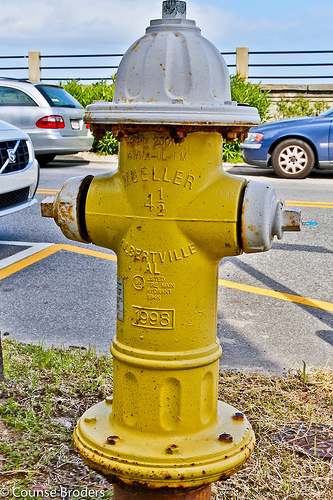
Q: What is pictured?
A: A hydrant.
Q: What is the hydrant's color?
A: Yellow.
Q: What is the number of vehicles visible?
A: Three.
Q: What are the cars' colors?
A: Blue and silver.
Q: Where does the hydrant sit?
A: Dried grass.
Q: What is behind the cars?
A: Green foliage.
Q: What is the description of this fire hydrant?
A: Yellow with white top and sides.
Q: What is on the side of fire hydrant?
A: Writing and year.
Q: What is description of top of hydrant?
A: White.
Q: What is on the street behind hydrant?
A: Yellow and white street markings.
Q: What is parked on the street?
A: Cars.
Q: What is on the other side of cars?
A: A metal rail with cement post.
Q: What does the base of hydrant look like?
A: Round with nuts and bolts.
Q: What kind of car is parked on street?
A: A van.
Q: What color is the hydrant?
A: Yellow.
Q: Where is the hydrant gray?
A: On top and on the ends.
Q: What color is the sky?
A: Blue.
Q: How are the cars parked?
A: In spaces along the road.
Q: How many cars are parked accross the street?
A: Two.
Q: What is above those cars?
A: A fence.